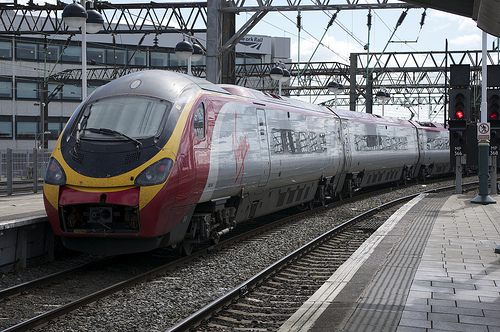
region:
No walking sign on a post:
[478, 122, 491, 134]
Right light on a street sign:
[449, 87, 467, 121]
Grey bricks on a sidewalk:
[431, 215, 491, 248]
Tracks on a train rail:
[209, 235, 324, 330]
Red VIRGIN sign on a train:
[221, 114, 257, 195]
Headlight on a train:
[135, 160, 170, 185]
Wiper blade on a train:
[83, 123, 143, 148]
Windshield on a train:
[78, 97, 168, 141]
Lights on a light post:
[61, 2, 102, 102]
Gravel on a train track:
[133, 283, 183, 319]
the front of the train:
[32, 81, 217, 263]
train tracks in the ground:
[215, 165, 435, 330]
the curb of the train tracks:
[287, 214, 395, 319]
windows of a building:
[4, 26, 201, 74]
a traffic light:
[439, 85, 481, 139]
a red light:
[447, 107, 472, 125]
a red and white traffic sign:
[470, 111, 497, 147]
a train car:
[314, 92, 439, 197]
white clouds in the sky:
[292, 25, 364, 78]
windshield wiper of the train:
[85, 115, 149, 157]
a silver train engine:
[41, 67, 344, 252]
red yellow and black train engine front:
[39, 66, 213, 243]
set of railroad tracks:
[159, 165, 480, 327]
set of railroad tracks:
[5, 233, 137, 326]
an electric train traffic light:
[445, 83, 471, 133]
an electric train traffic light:
[484, 88, 499, 136]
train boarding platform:
[289, 189, 498, 327]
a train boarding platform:
[3, 187, 58, 228]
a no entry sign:
[474, 118, 492, 147]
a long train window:
[263, 122, 327, 154]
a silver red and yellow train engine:
[39, 68, 342, 254]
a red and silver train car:
[330, 103, 422, 190]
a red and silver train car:
[418, 114, 452, 174]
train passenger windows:
[269, 126, 329, 152]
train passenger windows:
[347, 132, 408, 149]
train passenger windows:
[421, 135, 445, 147]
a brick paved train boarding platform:
[321, 182, 498, 327]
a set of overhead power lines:
[216, 6, 412, 74]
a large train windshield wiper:
[71, 120, 141, 143]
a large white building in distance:
[2, 24, 292, 184]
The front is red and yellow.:
[46, 67, 224, 254]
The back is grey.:
[180, 80, 496, 231]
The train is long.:
[47, 59, 494, 249]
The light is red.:
[428, 74, 474, 195]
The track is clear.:
[86, 244, 283, 329]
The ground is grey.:
[422, 249, 467, 324]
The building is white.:
[5, 8, 328, 174]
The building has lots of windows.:
[2, 8, 304, 213]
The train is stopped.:
[43, 35, 493, 219]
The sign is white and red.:
[432, 67, 498, 197]